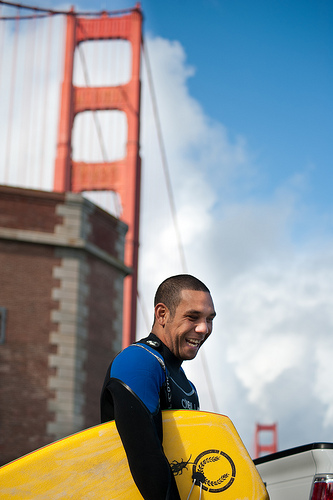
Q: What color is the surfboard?
A: Yellow.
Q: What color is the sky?
A: Blue.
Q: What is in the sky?
A: Clouds.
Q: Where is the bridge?
A: Behind the man.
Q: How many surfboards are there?
A: One.